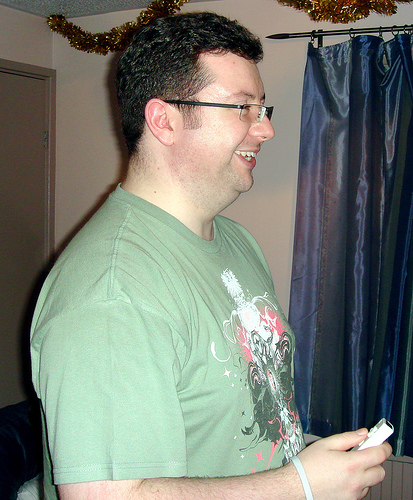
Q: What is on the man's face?
A: Glasses.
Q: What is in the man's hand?
A: A game controller.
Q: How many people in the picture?
A: One.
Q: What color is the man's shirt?
A: Green.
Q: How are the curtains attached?
A: With rings.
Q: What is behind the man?
A: A door.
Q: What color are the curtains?
A: Blue.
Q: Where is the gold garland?
A: On the ceiling.